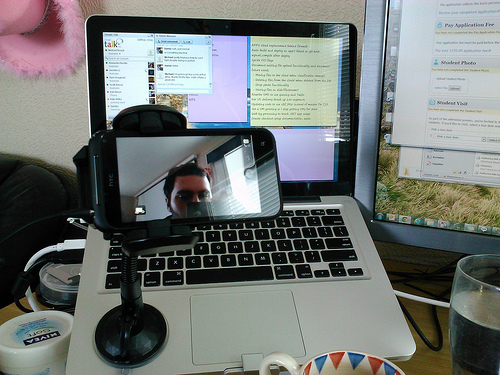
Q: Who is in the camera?
A: A man.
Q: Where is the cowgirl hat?
A: On the wall.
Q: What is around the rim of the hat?
A: Feathers.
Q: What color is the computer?
A: Gray.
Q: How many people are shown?
A: 1.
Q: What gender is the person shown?
A: Male.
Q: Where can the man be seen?
A: Mirror.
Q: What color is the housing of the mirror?
A: Black.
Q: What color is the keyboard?
A: Black.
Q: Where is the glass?
A: Right side.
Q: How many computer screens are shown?
A: 2.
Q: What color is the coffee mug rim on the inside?
A: Red and blue.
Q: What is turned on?
A: Computer screens.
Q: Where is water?
A: In a glass.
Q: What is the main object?
A: A laptop.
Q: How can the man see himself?
A: Webcam.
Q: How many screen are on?
A: Two.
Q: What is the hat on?
A: The wall.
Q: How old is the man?
A: Young.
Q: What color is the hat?
A: Pink.